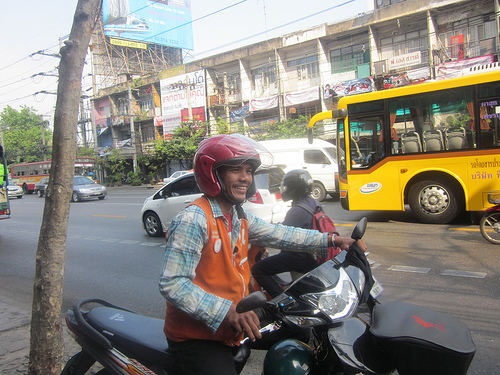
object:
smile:
[232, 183, 249, 193]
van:
[253, 137, 345, 201]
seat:
[88, 306, 170, 364]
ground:
[420, 115, 453, 149]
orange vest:
[163, 197, 253, 345]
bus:
[11, 157, 101, 194]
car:
[140, 164, 293, 237]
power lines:
[0, 0, 357, 117]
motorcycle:
[55, 216, 476, 375]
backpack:
[291, 201, 340, 266]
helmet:
[192, 133, 274, 206]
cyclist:
[157, 132, 367, 374]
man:
[251, 169, 342, 299]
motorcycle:
[218, 227, 380, 299]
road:
[0, 182, 499, 375]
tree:
[161, 119, 215, 171]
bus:
[306, 61, 500, 224]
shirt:
[157, 194, 330, 348]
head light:
[285, 264, 366, 327]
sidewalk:
[0, 308, 126, 375]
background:
[302, 56, 485, 226]